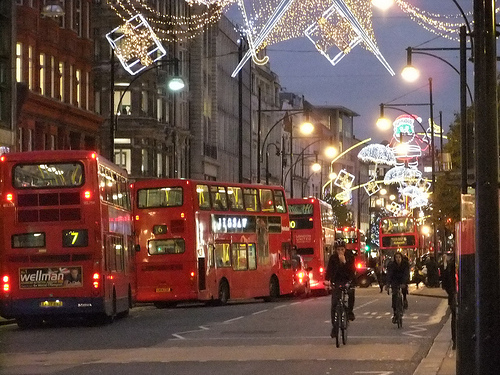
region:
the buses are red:
[1, 127, 438, 371]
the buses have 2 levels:
[7, 116, 424, 310]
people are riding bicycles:
[296, 205, 424, 358]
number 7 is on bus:
[70, 221, 93, 252]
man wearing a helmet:
[326, 236, 353, 263]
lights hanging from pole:
[99, 1, 486, 103]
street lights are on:
[144, 40, 441, 153]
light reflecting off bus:
[186, 198, 283, 258]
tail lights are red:
[0, 268, 122, 298]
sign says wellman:
[16, 266, 92, 298]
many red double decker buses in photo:
[37, 114, 447, 342]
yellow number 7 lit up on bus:
[60, 211, 98, 262]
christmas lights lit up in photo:
[101, 1, 442, 83]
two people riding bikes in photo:
[318, 212, 423, 357]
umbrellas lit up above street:
[351, 107, 442, 222]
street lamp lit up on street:
[378, 30, 463, 102]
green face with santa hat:
[388, 111, 426, 156]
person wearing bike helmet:
[330, 228, 361, 265]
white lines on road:
[142, 284, 460, 362]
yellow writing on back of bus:
[371, 234, 422, 252]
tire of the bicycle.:
[332, 308, 345, 345]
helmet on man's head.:
[330, 238, 349, 250]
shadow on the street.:
[139, 311, 156, 342]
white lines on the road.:
[180, 312, 235, 357]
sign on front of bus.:
[21, 261, 86, 288]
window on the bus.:
[22, 165, 72, 182]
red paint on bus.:
[143, 267, 181, 280]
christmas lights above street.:
[392, 120, 418, 153]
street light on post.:
[300, 121, 315, 131]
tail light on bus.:
[184, 270, 200, 280]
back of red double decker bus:
[8, 144, 132, 361]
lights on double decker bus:
[4, 150, 127, 319]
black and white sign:
[9, 265, 112, 298]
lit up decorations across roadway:
[87, 4, 467, 78]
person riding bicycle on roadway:
[309, 224, 368, 372]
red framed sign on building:
[367, 206, 432, 262]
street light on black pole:
[389, 30, 499, 189]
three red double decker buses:
[28, 141, 348, 298]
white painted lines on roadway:
[187, 304, 453, 354]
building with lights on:
[22, 40, 112, 138]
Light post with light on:
[400, 25, 479, 192]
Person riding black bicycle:
[322, 237, 364, 352]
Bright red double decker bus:
[133, 173, 303, 305]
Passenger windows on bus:
[194, 185, 243, 210]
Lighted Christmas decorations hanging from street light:
[333, 113, 435, 211]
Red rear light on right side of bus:
[82, 188, 92, 200]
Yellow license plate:
[37, 297, 69, 311]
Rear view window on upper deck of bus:
[9, 157, 90, 191]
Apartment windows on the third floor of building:
[116, 78, 186, 133]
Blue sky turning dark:
[289, 67, 446, 114]